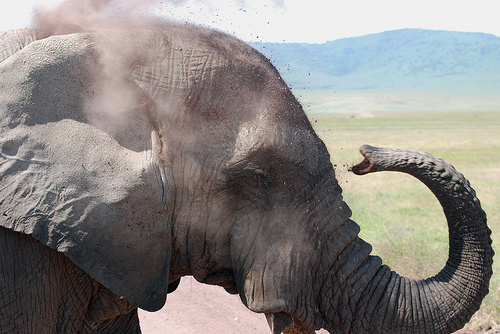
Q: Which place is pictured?
A: It is a field.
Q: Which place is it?
A: It is a field.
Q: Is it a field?
A: Yes, it is a field.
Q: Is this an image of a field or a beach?
A: It is showing a field.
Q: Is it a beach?
A: No, it is a field.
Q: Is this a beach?
A: No, it is a field.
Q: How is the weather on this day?
A: It is cloudless.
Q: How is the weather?
A: It is cloudless.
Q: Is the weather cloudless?
A: Yes, it is cloudless.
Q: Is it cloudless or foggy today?
A: It is cloudless.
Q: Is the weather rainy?
A: No, it is cloudless.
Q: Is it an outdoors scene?
A: Yes, it is outdoors.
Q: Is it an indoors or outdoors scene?
A: It is outdoors.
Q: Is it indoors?
A: No, it is outdoors.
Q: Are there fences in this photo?
A: No, there are no fences.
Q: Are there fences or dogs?
A: No, there are no fences or dogs.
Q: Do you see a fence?
A: No, there are no fences.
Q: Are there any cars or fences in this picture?
A: No, there are no fences or cars.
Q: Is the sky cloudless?
A: Yes, the sky is cloudless.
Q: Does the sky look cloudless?
A: Yes, the sky is cloudless.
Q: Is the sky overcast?
A: No, the sky is cloudless.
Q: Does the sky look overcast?
A: No, the sky is cloudless.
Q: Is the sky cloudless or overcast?
A: The sky is cloudless.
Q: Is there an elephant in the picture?
A: Yes, there is an elephant.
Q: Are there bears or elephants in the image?
A: Yes, there is an elephant.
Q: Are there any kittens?
A: No, there are no kittens.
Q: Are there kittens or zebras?
A: No, there are no kittens or zebras.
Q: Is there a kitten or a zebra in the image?
A: No, there are no kittens or zebras.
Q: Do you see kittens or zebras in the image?
A: No, there are no kittens or zebras.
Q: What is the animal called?
A: The animal is an elephant.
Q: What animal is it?
A: The animal is an elephant.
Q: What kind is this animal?
A: This is an elephant.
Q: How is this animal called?
A: This is an elephant.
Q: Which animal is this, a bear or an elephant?
A: This is an elephant.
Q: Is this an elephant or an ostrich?
A: This is an elephant.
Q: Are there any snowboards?
A: No, there are no snowboards.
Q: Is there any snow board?
A: No, there are no snowboards.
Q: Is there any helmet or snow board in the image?
A: No, there are no snowboards or helmets.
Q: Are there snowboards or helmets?
A: No, there are no snowboards or helmets.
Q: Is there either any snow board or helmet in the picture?
A: No, there are no snowboards or helmets.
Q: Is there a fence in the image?
A: No, there are no fences.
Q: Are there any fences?
A: No, there are no fences.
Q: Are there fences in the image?
A: No, there are no fences.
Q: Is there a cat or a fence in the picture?
A: No, there are no fences or cats.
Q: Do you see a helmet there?
A: No, there are no helmets.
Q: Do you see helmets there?
A: No, there are no helmets.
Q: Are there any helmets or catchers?
A: No, there are no helmets or catchers.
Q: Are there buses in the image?
A: No, there are no buses.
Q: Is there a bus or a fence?
A: No, there are no buses or fences.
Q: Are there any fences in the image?
A: No, there are no fences.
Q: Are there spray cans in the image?
A: No, there are no spray cans.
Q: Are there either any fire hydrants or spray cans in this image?
A: No, there are no spray cans or fire hydrants.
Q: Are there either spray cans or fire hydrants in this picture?
A: No, there are no spray cans or fire hydrants.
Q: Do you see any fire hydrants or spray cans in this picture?
A: No, there are no spray cans or fire hydrants.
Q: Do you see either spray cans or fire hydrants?
A: No, there are no spray cans or fire hydrants.